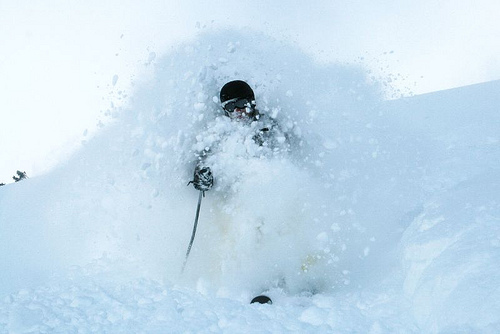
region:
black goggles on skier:
[222, 95, 250, 111]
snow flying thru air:
[103, 59, 158, 189]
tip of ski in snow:
[245, 287, 272, 310]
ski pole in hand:
[175, 165, 218, 294]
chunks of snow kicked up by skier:
[335, 41, 442, 181]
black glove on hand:
[191, 158, 211, 195]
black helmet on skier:
[213, 80, 256, 101]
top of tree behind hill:
[0, 165, 30, 190]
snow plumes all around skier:
[101, 20, 416, 310]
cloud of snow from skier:
[224, 173, 326, 274]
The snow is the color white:
[338, 97, 484, 309]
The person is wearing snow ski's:
[236, 253, 316, 319]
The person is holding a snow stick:
[171, 156, 216, 288]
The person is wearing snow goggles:
[213, 95, 263, 115]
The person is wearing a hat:
[213, 77, 258, 118]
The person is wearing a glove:
[188, 163, 218, 196]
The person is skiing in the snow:
[153, 59, 332, 324]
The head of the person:
[214, 78, 263, 122]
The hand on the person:
[186, 160, 216, 198]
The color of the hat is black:
[214, 75, 259, 117]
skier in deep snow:
[189, 81, 301, 261]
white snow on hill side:
[69, 225, 110, 258]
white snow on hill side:
[362, 105, 410, 136]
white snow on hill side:
[381, 118, 435, 158]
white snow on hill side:
[312, 85, 384, 139]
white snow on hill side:
[370, 64, 412, 111]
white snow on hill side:
[34, 217, 114, 282]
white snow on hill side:
[30, 271, 96, 318]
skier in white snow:
[175, 73, 312, 308]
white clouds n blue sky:
[11, 33, 61, 67]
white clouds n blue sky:
[22, 65, 46, 95]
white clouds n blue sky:
[0, 102, 60, 156]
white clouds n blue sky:
[44, 15, 84, 52]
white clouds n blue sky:
[61, 53, 113, 90]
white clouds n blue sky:
[411, 28, 466, 65]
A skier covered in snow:
[31, 30, 450, 332]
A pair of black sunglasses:
[214, 97, 267, 118]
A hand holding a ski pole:
[183, 159, 238, 208]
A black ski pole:
[172, 194, 217, 281]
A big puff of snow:
[112, 25, 402, 305]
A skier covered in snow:
[128, 67, 357, 324]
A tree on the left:
[6, 145, 27, 199]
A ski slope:
[28, 95, 488, 290]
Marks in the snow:
[391, 164, 457, 292]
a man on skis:
[166, 66, 318, 313]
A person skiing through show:
[92, 8, 389, 315]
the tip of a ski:
[247, 290, 276, 307]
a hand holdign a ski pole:
[145, 150, 215, 280]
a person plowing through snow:
[63, 16, 415, 311]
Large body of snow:
[408, 119, 490, 221]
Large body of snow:
[393, 215, 482, 320]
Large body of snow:
[383, 115, 475, 200]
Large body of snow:
[20, 265, 132, 328]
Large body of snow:
[378, 202, 471, 307]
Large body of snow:
[341, 233, 436, 323]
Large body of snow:
[356, 234, 436, 317]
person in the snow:
[135, 63, 351, 330]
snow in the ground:
[5, 58, 493, 332]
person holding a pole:
[175, 125, 217, 282]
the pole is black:
[170, 165, 216, 293]